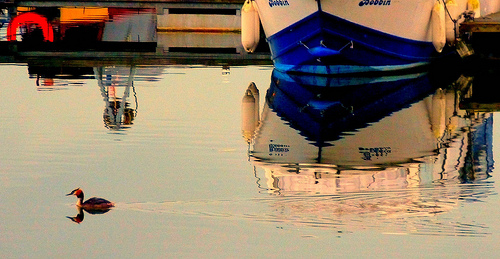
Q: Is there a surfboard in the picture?
A: No, there are no surfboards.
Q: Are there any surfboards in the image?
A: No, there are no surfboards.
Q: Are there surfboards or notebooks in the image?
A: No, there are no surfboards or notebooks.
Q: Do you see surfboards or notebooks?
A: No, there are no surfboards or notebooks.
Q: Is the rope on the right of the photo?
A: Yes, the rope is on the right of the image.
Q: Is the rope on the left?
A: No, the rope is on the right of the image.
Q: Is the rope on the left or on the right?
A: The rope is on the right of the image.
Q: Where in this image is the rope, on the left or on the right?
A: The rope is on the right of the image.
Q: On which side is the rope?
A: The rope is on the right of the image.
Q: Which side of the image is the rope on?
A: The rope is on the right of the image.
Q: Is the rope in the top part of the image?
A: Yes, the rope is in the top of the image.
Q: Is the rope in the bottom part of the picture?
A: No, the rope is in the top of the image.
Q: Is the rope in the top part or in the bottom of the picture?
A: The rope is in the top of the image.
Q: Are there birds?
A: Yes, there is a bird.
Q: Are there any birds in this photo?
A: Yes, there is a bird.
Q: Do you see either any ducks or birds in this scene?
A: Yes, there is a bird.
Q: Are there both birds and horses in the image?
A: No, there is a bird but no horses.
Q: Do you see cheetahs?
A: No, there are no cheetahs.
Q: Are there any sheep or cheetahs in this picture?
A: No, there are no cheetahs or sheep.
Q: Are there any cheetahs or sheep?
A: No, there are no cheetahs or sheep.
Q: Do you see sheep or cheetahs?
A: No, there are no cheetahs or sheep.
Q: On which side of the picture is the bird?
A: The bird is on the left of the image.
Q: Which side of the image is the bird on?
A: The bird is on the left of the image.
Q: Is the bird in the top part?
A: No, the bird is in the bottom of the image.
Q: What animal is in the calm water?
A: The bird is in the water.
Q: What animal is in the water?
A: The bird is in the water.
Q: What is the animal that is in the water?
A: The animal is a bird.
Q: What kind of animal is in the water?
A: The animal is a bird.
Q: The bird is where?
A: The bird is in the water.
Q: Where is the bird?
A: The bird is in the water.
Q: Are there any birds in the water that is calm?
A: Yes, there is a bird in the water.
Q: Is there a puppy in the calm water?
A: No, there is a bird in the water.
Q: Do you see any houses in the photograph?
A: No, there are no houses.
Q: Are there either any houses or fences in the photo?
A: No, there are no houses or fences.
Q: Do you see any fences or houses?
A: No, there are no houses or fences.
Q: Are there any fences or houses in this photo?
A: No, there are no houses or fences.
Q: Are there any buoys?
A: Yes, there is a buoy.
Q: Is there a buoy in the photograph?
A: Yes, there is a buoy.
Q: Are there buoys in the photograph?
A: Yes, there is a buoy.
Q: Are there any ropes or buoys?
A: Yes, there is a buoy.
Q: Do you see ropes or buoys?
A: Yes, there is a buoy.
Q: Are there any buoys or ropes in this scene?
A: Yes, there is a buoy.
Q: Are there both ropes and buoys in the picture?
A: Yes, there are both a buoy and a rope.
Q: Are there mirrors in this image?
A: No, there are no mirrors.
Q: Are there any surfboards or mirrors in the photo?
A: No, there are no mirrors or surfboards.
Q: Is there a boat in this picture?
A: Yes, there is a boat.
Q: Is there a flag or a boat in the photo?
A: Yes, there is a boat.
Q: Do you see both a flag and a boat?
A: No, there is a boat but no flags.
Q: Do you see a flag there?
A: No, there are no flags.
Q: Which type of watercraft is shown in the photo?
A: The watercraft is a boat.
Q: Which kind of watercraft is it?
A: The watercraft is a boat.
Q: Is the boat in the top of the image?
A: Yes, the boat is in the top of the image.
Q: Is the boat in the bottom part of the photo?
A: No, the boat is in the top of the image.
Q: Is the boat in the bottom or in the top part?
A: The boat is in the top of the image.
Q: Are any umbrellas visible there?
A: No, there are no umbrellas.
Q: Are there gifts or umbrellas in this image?
A: No, there are no umbrellas or gifts.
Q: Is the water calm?
A: Yes, the water is calm.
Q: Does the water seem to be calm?
A: Yes, the water is calm.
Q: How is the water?
A: The water is calm.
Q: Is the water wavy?
A: No, the water is calm.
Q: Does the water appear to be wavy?
A: No, the water is calm.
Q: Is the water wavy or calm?
A: The water is calm.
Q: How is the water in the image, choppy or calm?
A: The water is calm.